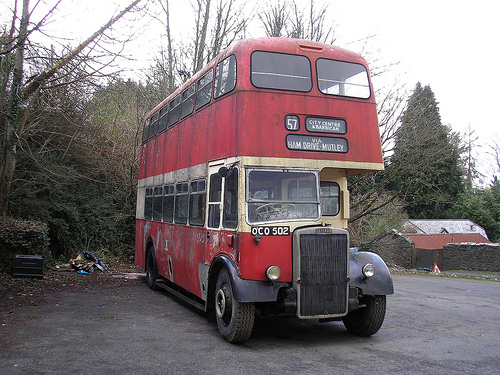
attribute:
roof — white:
[391, 210, 494, 245]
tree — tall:
[373, 76, 467, 217]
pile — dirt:
[59, 242, 120, 275]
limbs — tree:
[5, 219, 43, 246]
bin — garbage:
[8, 216, 52, 286]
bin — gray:
[5, 216, 51, 278]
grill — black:
[296, 229, 354, 321]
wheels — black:
[209, 272, 393, 337]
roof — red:
[398, 230, 496, 245]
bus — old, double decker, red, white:
[121, 38, 411, 348]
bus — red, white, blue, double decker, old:
[132, 30, 397, 338]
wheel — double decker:
[207, 264, 261, 351]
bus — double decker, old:
[96, 30, 397, 343]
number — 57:
[283, 111, 303, 130]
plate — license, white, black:
[250, 218, 287, 235]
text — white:
[275, 106, 355, 156]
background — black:
[282, 100, 353, 152]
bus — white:
[140, 27, 402, 355]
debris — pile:
[57, 240, 117, 282]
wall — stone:
[370, 234, 498, 285]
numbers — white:
[288, 111, 302, 127]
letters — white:
[286, 129, 354, 152]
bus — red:
[102, 16, 422, 344]